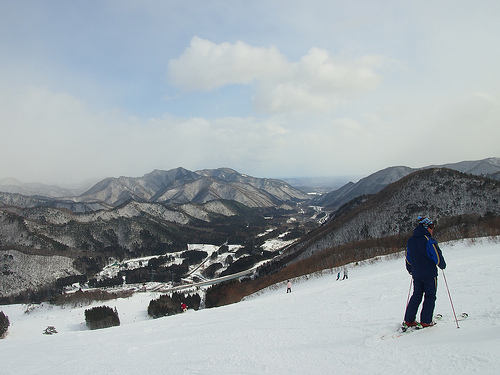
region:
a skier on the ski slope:
[396, 213, 468, 331]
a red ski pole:
[440, 264, 461, 330]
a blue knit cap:
[417, 213, 433, 230]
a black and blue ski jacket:
[404, 228, 444, 277]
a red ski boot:
[401, 318, 419, 332]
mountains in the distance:
[1, 167, 309, 227]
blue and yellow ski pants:
[402, 270, 439, 324]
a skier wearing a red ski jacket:
[178, 300, 190, 312]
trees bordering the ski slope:
[206, 233, 401, 307]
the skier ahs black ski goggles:
[424, 221, 434, 230]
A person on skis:
[400, 215, 466, 328]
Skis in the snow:
[393, 310, 466, 337]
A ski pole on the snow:
[440, 265, 461, 328]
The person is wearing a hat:
[414, 209, 430, 222]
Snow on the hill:
[0, 247, 498, 374]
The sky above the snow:
[1, 2, 499, 168]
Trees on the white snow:
[86, 304, 118, 331]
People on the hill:
[284, 267, 350, 292]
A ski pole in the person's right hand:
[437, 255, 461, 327]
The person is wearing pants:
[403, 275, 436, 326]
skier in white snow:
[383, 190, 451, 332]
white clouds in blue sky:
[11, 33, 98, 80]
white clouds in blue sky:
[70, 50, 122, 88]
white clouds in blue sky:
[190, 104, 231, 144]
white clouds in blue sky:
[250, 34, 280, 71]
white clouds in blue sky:
[343, 44, 408, 109]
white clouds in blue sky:
[184, 56, 241, 126]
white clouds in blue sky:
[366, 43, 453, 107]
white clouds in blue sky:
[93, 66, 137, 116]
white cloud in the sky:
[166, 26, 293, 98]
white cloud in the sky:
[7, 79, 299, 185]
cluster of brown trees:
[37, 285, 130, 312]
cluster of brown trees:
[118, 262, 182, 288]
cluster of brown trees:
[209, 248, 259, 273]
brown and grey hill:
[259, 164, 496, 274]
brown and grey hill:
[25, 201, 77, 227]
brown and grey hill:
[6, 239, 78, 296]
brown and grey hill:
[204, 199, 257, 222]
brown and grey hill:
[330, 159, 414, 203]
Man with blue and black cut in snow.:
[412, 202, 449, 303]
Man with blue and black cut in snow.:
[346, 339, 390, 367]